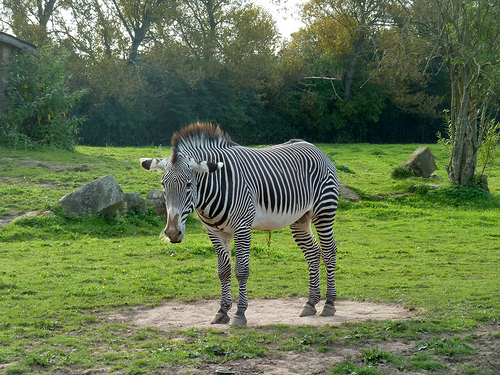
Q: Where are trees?
A: In background.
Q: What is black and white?
A: Zebra.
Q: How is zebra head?
A: Lowered.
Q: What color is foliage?
A: Green.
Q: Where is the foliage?
A: On trees.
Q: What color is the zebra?
A: Black and white.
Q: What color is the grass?
A: Green.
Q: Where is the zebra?
A: On the dirt.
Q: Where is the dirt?
A: Under the zebra.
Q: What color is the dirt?
A: Brown.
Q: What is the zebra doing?
A: Standing.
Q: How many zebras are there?
A: One.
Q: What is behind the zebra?
A: Trees.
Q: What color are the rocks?
A: Gray.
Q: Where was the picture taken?
A: In a zoo.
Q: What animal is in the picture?
A: A zebra.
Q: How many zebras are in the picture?
A: 1.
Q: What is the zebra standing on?
A: Dirt.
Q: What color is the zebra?
A: Black and white.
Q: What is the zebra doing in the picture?
A: Standing.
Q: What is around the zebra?
A: Grass.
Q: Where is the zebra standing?
A: In the dirt.